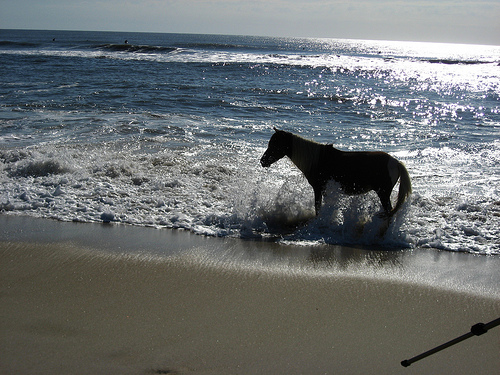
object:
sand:
[2, 217, 499, 374]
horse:
[256, 126, 413, 239]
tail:
[391, 161, 413, 223]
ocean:
[3, 30, 500, 254]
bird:
[120, 38, 127, 44]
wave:
[2, 48, 500, 253]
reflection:
[308, 34, 500, 91]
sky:
[1, 1, 500, 45]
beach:
[0, 216, 499, 375]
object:
[461, 206, 499, 285]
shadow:
[396, 318, 498, 368]